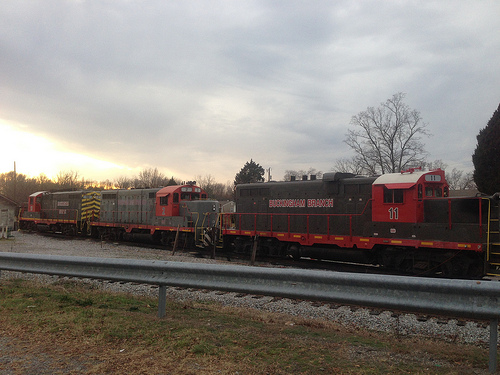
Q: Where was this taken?
A: On a road beside a train track.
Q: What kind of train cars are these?
A: Engines.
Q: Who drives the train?
A: Engineer.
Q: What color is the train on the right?
A: Red and black.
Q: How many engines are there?
A: Three.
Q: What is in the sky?
A: Clouds.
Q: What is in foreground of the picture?
A: Guardrail.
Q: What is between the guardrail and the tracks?
A: Gravel.